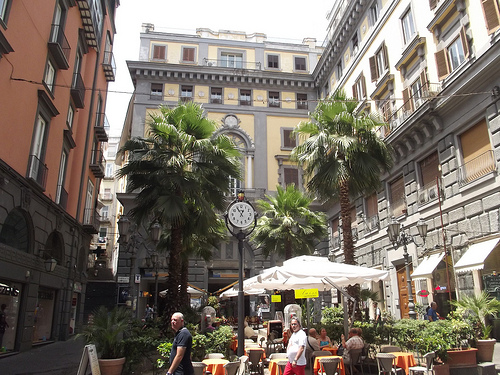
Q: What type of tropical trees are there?
A: Palm trees.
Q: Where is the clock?
A: On a pole.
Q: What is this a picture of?
A: An outdoor restaurant.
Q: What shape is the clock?
A: Round.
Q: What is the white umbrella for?
A: To create shade.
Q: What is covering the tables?
A: Orange table clothes.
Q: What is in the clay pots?
A: Plants.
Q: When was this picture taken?
A: During the day time.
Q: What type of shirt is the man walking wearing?
A: Black t-shirt.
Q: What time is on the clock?
A: 12:55.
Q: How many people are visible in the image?
A: Two.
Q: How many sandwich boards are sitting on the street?
A: One.